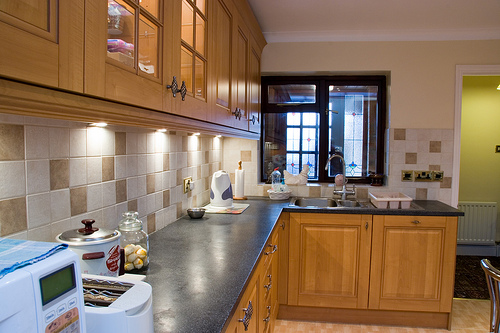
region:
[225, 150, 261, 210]
The paper towel holder is wooden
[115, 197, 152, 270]
this is a glass jar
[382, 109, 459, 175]
the tiles are brown and white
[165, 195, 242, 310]
the counter top is black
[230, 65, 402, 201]
two window are over the sink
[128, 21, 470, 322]
this is the kitchen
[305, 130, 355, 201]
the faucet is silver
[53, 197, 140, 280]
this is a rice cooker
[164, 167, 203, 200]
this is an outlet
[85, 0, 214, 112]
the cabinets have windows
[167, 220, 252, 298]
A granite counter top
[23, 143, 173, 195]
A tiled wall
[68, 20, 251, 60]
glass and wood cabinets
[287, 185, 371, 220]
A silver sink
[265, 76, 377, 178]
A window looking outside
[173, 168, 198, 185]
an electrical outlet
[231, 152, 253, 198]
a roll of paper towels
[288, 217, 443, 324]
a set of wooden cabinets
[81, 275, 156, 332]
A white toaster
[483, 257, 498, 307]
The back of a wooden chair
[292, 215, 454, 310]
this is a drawer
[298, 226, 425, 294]
the drawer is brown in color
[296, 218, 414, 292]
the door is wooden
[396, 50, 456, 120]
this is a wall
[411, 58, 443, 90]
the wall is cream in color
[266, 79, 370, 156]
this is a window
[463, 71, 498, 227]
this is a door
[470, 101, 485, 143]
the door is opened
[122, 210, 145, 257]
this is a container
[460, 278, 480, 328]
this is the floor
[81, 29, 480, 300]
What a beautiful kitchen!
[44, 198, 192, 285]
Canister filled with goodies.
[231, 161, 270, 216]
Paper towels on counter.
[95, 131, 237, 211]
Beautiful wall tiles.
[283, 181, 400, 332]
Nice cabinets.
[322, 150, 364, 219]
Look at that faucet.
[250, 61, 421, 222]
Nice window above the sink.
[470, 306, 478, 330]
Is the floor wood or laminate?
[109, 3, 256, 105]
Love the glass windows in the cabinets.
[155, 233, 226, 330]
Kitchen counter needs wiped down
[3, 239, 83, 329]
Microwave with a digital clock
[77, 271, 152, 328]
White toaster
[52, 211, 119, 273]
A white and red crock pot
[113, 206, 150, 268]
A clear glass jar with snacks inside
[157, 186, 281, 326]
Black and white speckled counter tops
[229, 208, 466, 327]
The wooden cabinets have dark metal knobs and handles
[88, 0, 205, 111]
Two cabinets have glass window panes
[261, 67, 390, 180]
Two windows in the kitchen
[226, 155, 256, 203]
Wooden paper towel holder with paper towels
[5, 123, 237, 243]
Tile back splash is white and brown tiles